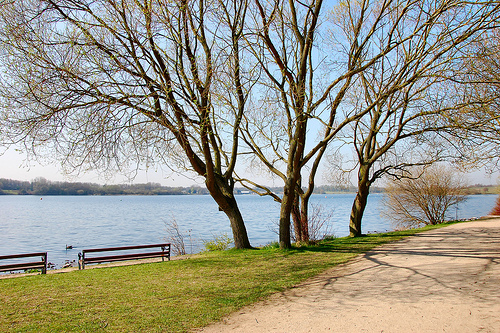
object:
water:
[0, 191, 499, 276]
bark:
[225, 202, 237, 213]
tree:
[1, 1, 255, 250]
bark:
[281, 227, 289, 237]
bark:
[298, 217, 303, 233]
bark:
[301, 206, 306, 219]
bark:
[350, 211, 364, 219]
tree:
[371, 143, 498, 249]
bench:
[0, 251, 50, 278]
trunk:
[276, 199, 293, 249]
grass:
[0, 218, 467, 331]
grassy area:
[0, 221, 461, 332]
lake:
[1, 191, 500, 275]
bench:
[75, 241, 171, 270]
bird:
[64, 242, 75, 251]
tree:
[303, 0, 499, 241]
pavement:
[188, 215, 499, 332]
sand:
[190, 217, 500, 333]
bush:
[378, 161, 473, 232]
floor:
[0, 212, 499, 332]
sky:
[0, 0, 499, 187]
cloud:
[0, 0, 499, 192]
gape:
[81, 242, 170, 259]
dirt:
[200, 216, 499, 332]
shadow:
[267, 223, 500, 312]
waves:
[0, 190, 499, 272]